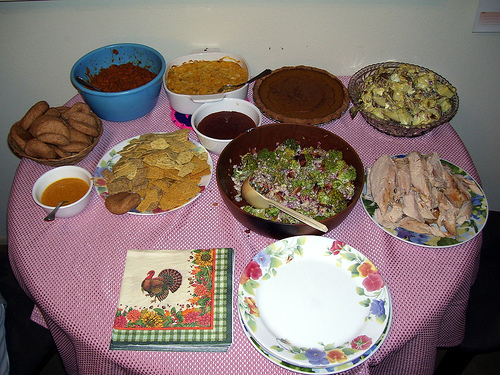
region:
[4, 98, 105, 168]
The basket is filled with bread rolls.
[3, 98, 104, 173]
The basket is round.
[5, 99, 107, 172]
The basket is brown.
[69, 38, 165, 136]
The bowl is blue.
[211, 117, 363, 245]
The bowl is burgundy.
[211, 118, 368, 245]
The bowl is large.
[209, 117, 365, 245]
The bowl is in use.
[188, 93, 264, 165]
The bowl is white.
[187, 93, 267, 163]
The bowl is full.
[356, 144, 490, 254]
The plate is filled with meat.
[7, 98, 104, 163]
A bowl of brown vegetables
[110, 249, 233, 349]
A set of napkins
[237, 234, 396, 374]
A couple of plates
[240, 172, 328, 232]
A utencil in a bowl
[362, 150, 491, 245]
A plate with dried turkey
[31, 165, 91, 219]
A bowl of a condiment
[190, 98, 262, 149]
A bowl of brown liquid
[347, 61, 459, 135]
A dish full of food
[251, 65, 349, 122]
A pumpkin pie on a table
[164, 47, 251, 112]
a bowl of orange soup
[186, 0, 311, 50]
this is the wall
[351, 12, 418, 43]
the wall is white in color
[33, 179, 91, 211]
this is a cup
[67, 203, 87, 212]
the cup is white in color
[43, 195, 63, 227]
this is a spoon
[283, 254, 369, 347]
this is a plate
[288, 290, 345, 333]
the plate is white in color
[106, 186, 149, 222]
this is a snack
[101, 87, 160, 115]
this is a bowl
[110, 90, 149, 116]
the bowl is blue in color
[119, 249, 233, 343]
napkins on the table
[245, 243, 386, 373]
plates on the table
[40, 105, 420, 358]
a red table cloth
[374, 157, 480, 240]
a plate of meat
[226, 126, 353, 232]
a bowl of salad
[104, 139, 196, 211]
a plate of crackers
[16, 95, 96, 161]
a bowl of rolls of bread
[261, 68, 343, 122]
a pie on the table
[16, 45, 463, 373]
a table with food on it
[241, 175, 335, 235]
a spoon in the salad